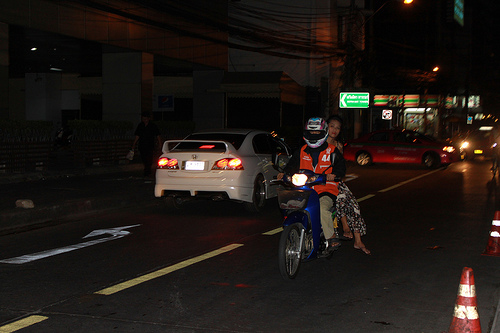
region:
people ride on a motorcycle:
[268, 109, 374, 285]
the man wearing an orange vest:
[300, 141, 340, 196]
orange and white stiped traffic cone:
[446, 260, 486, 331]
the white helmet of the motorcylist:
[298, 118, 329, 149]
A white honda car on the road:
[153, 120, 283, 209]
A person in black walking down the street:
[120, 103, 170, 182]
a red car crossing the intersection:
[344, 131, 457, 176]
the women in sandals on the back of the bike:
[338, 230, 375, 259]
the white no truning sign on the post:
[381, 106, 391, 118]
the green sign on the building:
[333, 88, 376, 114]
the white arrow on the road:
[2, 223, 139, 263]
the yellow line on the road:
[1, 313, 47, 331]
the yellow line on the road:
[94, 242, 243, 294]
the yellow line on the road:
[263, 225, 282, 235]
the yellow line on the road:
[353, 193, 374, 203]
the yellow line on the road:
[382, 161, 447, 190]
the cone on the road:
[451, 265, 481, 331]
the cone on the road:
[478, 211, 498, 254]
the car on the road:
[153, 126, 295, 205]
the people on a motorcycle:
[276, 114, 371, 279]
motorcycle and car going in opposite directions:
[143, 52, 373, 273]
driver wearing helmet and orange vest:
[280, 106, 342, 258]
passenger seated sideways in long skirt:
[325, 115, 370, 255]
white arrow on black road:
[10, 195, 140, 275]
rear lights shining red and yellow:
[151, 150, 241, 175]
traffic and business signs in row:
[332, 70, 482, 110]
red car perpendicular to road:
[345, 125, 450, 170]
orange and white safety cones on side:
[440, 197, 495, 327]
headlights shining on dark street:
[455, 110, 495, 165]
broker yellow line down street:
[5, 157, 480, 327]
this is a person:
[278, 100, 340, 264]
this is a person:
[324, 110, 369, 256]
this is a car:
[121, 95, 270, 239]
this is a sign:
[331, 83, 371, 116]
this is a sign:
[374, 99, 395, 128]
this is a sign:
[397, 105, 422, 130]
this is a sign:
[469, 94, 480, 111]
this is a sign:
[369, 90, 396, 121]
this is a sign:
[399, 89, 421, 121]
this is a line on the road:
[87, 220, 259, 303]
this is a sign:
[416, 240, 483, 328]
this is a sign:
[321, 78, 378, 125]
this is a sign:
[404, 88, 429, 116]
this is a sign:
[431, 82, 462, 112]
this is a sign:
[399, 106, 437, 138]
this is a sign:
[470, 86, 492, 119]